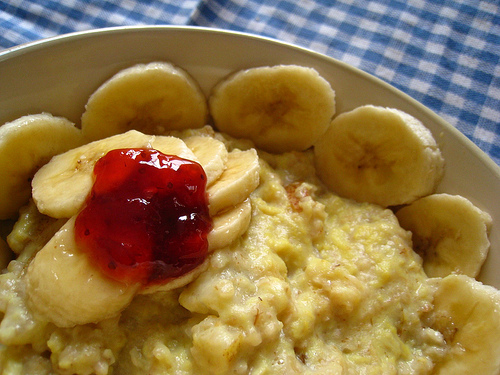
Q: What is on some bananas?
A: Strawberry jam.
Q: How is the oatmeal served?
A: In a bowl.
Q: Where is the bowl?
A: On the table.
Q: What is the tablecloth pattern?
A: Gingham.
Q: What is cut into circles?
A: Banana.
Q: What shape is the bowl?
A: Circular.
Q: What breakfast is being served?
A: Oatmeal.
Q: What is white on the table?
A: Bowl.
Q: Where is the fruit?
A: In the bowl.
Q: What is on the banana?
A: Jam.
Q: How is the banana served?
A: Sliced.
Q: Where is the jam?
A: On the bananas.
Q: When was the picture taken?
A: Breakfast.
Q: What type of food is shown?
A: Oatmeal.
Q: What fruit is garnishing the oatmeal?
A: Banana.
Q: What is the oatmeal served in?
A: A white bowl.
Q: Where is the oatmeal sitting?
A: A table.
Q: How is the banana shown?
A: Sliced.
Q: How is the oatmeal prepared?
A: Cooked.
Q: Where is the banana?
A: In the bowl.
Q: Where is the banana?
A: In the white bowl.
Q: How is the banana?
A: Sliced in white bowl.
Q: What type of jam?
A: Strawberry jam.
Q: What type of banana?
A: A round banana.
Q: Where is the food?
A: In a round bowl.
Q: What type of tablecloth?
A: Blue and white cloth.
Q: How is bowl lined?
A: With banana slices.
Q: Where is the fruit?
A: On the oatmeal.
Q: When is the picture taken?
A: At breakfast time.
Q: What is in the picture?
A: Oatmeal with bananas and jam.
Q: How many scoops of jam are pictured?
A: One.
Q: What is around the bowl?
A: Bananas.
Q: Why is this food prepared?
A: For someone to eat it.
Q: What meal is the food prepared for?
A: Breakfast.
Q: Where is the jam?
A: On top of the bananas.